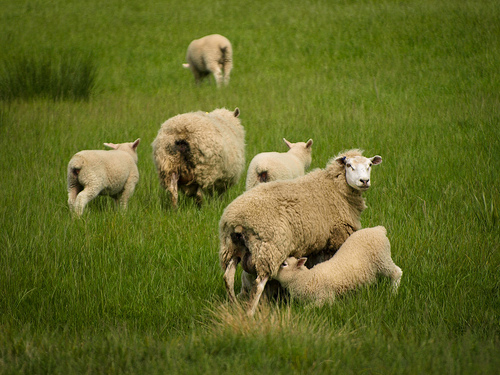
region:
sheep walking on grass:
[166, 18, 238, 93]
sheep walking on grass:
[146, 69, 277, 233]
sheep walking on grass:
[55, 128, 157, 226]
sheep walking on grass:
[227, 118, 347, 209]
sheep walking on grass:
[234, 135, 382, 325]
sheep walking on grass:
[279, 238, 476, 350]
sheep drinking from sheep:
[208, 155, 422, 318]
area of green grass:
[52, 295, 119, 335]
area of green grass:
[15, 37, 89, 103]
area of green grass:
[313, 30, 415, 98]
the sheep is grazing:
[187, 33, 235, 83]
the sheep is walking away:
[71, 138, 139, 208]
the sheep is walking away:
[248, 137, 315, 191]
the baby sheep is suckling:
[279, 225, 403, 315]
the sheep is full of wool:
[228, 160, 363, 286]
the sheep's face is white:
[346, 155, 378, 190]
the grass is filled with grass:
[1, 1, 498, 368]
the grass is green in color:
[1, 1, 497, 371]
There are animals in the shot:
[40, 64, 422, 336]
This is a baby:
[248, 217, 411, 325]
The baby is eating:
[249, 223, 429, 325]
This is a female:
[200, 138, 419, 285]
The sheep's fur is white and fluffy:
[141, 67, 250, 212]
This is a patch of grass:
[8, 39, 114, 109]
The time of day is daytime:
[11, 8, 479, 325]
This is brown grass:
[169, 276, 324, 363]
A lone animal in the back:
[164, 20, 272, 92]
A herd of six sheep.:
[55, 34, 406, 324]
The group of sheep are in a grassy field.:
[2, 1, 497, 373]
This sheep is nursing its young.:
[212, 143, 404, 320]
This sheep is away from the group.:
[180, 32, 237, 90]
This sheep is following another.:
[61, 138, 141, 220]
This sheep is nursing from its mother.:
[271, 219, 406, 315]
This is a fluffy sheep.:
[149, 102, 246, 213]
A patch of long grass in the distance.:
[2, 40, 105, 112]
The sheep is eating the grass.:
[180, 31, 233, 92]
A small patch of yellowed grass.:
[200, 291, 305, 341]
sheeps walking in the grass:
[59, 25, 447, 340]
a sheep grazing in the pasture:
[176, 25, 246, 109]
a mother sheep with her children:
[57, 80, 329, 237]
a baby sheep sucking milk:
[262, 223, 411, 322]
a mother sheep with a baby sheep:
[212, 138, 417, 332]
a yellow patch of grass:
[197, 286, 316, 361]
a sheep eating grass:
[167, 29, 249, 97]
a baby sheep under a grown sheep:
[200, 145, 452, 332]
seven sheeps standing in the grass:
[51, 24, 425, 352]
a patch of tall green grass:
[2, 23, 109, 118]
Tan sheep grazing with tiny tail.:
[180, 34, 233, 88]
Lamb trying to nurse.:
[271, 226, 401, 313]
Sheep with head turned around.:
[211, 147, 383, 320]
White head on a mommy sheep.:
[336, 153, 381, 190]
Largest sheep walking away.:
[150, 108, 245, 210]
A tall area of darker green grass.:
[2, 46, 99, 101]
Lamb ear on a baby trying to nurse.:
[296, 256, 307, 268]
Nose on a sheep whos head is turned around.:
[358, 177, 368, 184]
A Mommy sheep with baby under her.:
[218, 149, 384, 318]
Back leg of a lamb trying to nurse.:
[375, 252, 403, 296]